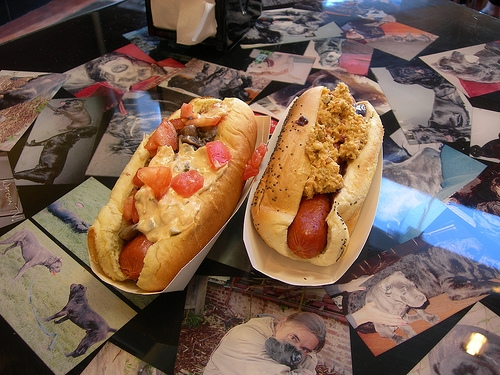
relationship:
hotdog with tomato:
[148, 106, 223, 264] [205, 137, 225, 175]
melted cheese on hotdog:
[132, 140, 227, 242] [148, 106, 223, 264]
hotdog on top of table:
[249, 80, 385, 266] [0, 0, 498, 374]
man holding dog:
[253, 308, 324, 374] [263, 334, 307, 373]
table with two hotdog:
[0, 0, 498, 374] [249, 80, 385, 266]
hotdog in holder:
[253, 36, 371, 267] [235, 233, 301, 307]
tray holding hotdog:
[135, 263, 197, 298] [148, 106, 223, 264]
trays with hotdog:
[81, 167, 299, 283] [249, 80, 385, 266]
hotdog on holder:
[148, 106, 223, 264] [235, 233, 301, 307]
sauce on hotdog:
[340, 103, 361, 154] [253, 36, 371, 267]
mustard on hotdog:
[328, 108, 372, 143] [253, 36, 371, 267]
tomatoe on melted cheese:
[135, 169, 176, 198] [132, 140, 227, 242]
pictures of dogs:
[324, 30, 483, 169] [413, 69, 482, 202]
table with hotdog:
[0, 0, 498, 374] [249, 80, 385, 266]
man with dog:
[202, 310, 327, 374] [263, 334, 307, 373]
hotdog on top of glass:
[249, 80, 385, 266] [136, 330, 171, 361]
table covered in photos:
[0, 0, 498, 374] [49, 65, 137, 226]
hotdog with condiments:
[249, 80, 385, 266] [151, 133, 232, 224]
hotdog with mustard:
[253, 36, 371, 267] [328, 108, 372, 143]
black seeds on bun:
[268, 141, 293, 205] [330, 104, 365, 262]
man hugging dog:
[253, 308, 324, 374] [263, 334, 307, 373]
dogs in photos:
[413, 69, 482, 202] [49, 65, 137, 226]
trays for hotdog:
[241, 96, 384, 287] [253, 36, 371, 267]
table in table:
[4, 10, 128, 41] [0, 0, 498, 374]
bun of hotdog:
[330, 104, 365, 262] [253, 36, 371, 267]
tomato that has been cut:
[205, 137, 225, 175] [143, 163, 203, 197]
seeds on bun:
[265, 102, 301, 204] [330, 104, 365, 262]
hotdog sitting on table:
[249, 80, 385, 266] [0, 0, 498, 374]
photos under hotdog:
[49, 65, 137, 226] [249, 80, 385, 266]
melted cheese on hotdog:
[134, 160, 222, 278] [148, 106, 223, 264]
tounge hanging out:
[56, 100, 70, 113] [52, 99, 99, 124]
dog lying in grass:
[61, 194, 98, 237] [85, 192, 103, 209]